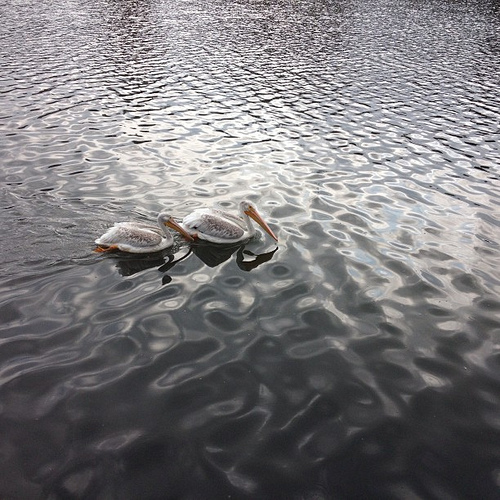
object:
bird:
[178, 200, 279, 245]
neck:
[242, 214, 256, 233]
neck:
[159, 222, 173, 239]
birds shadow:
[115, 242, 278, 286]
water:
[1, 0, 496, 193]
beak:
[244, 208, 279, 241]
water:
[116, 413, 263, 493]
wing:
[94, 226, 162, 247]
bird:
[91, 212, 195, 254]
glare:
[119, 122, 319, 207]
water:
[0, 1, 500, 498]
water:
[24, 23, 484, 473]